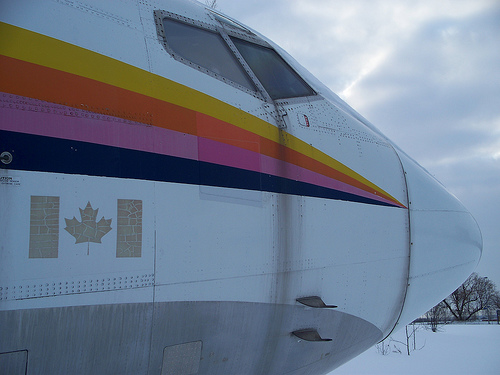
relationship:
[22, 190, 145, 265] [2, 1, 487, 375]
flag on plane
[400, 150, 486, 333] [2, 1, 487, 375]
nose of plane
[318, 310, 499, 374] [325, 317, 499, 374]
snow on ground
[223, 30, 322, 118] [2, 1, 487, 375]
window on plane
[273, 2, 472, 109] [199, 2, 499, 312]
clouds in sky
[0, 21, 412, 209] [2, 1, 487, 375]
stripe on plane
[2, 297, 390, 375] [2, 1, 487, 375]
bottom of plane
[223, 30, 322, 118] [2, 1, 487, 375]
window of plane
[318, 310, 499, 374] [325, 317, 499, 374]
snow covered ground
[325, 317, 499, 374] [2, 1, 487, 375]
ground behind plane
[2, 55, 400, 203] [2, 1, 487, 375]
stripe on plane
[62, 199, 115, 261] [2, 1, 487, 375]
leaf on plane